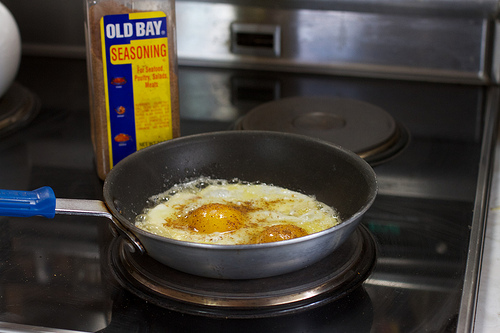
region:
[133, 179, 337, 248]
Two eggs cooking sunny side up.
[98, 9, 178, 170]
Traditional Old Bay label.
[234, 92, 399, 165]
Back burner of a stove.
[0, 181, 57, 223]
Restaurant quality protective covering pan handle.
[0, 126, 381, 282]
High quality teflon pan.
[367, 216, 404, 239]
Reflection on the top of an electric stove.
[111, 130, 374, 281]
Two eggs in a pan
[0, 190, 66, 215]
Blue handle of pan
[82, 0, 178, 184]
Bottle of Old Bay Seasoning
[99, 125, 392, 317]
Pan on the stove-top burner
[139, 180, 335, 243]
Two fried eggs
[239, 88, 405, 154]
Empty rear burner on stove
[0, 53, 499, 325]
Black stove top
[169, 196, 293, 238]
Seasoning on top of eggs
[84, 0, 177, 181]
Jar of seasoning on the stove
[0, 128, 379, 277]
Pan on stove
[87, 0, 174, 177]
bottle of Old Bay Seasoning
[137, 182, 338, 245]
fried eggs with Old Bay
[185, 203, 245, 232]
yolk of an egg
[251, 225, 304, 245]
yolk of an egg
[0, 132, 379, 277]
small frying pan with blue handle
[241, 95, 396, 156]
small metal stove plate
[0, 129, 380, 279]
frying pan filled with eggs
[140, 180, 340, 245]
two fried eggs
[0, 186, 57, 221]
blue plastic frying pan handle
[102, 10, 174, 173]
label on a bottle of seasoning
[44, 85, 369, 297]
eggs in a pan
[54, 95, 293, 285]
eggs in a frying pan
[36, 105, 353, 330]
eggsin a black pan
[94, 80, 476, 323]
pan that is cooking eggs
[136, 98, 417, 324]
pan with cooking eggs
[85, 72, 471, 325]
a black pan with cookings eggs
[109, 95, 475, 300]
black pan with eggs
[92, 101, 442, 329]
frying pan with eggs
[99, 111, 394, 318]
a black frying pan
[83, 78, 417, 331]
a pan on the stove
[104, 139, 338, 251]
Eggs frying in a pan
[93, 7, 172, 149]
Package of seasoning with blue and yellow label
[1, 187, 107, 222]
Blue plastic and silver metal pan handle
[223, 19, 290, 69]
Black panel with gray border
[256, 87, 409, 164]
Unused stove burner with black cover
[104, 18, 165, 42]
The words OLD BAY in white on blue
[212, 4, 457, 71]
Shiny metal stovetop panel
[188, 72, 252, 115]
Black surface reflecting shadows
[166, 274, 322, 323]
Edge of a stovetop burner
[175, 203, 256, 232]
Yellow egg yolk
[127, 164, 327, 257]
eggs cooking in a frying pan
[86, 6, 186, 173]
container of old bay seasoning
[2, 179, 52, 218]
blue handle of frying pan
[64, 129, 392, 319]
frying pan on stove burner